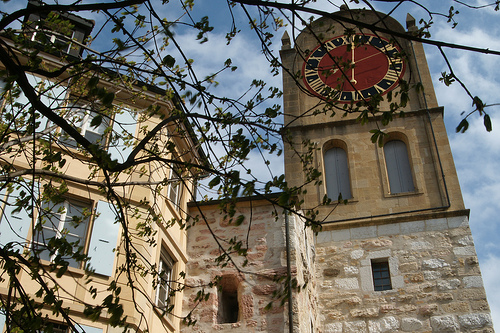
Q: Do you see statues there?
A: No, there are no statues.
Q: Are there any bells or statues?
A: No, there are no statues or bells.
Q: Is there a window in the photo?
A: Yes, there is a window.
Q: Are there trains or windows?
A: Yes, there is a window.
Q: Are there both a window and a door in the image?
A: No, there is a window but no doors.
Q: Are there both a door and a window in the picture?
A: No, there is a window but no doors.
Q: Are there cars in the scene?
A: No, there are no cars.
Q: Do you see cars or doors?
A: No, there are no cars or doors.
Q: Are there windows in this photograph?
A: Yes, there is a window.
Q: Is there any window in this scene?
A: Yes, there is a window.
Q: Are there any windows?
A: Yes, there is a window.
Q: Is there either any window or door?
A: Yes, there is a window.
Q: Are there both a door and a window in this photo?
A: No, there is a window but no doors.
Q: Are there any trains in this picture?
A: No, there are no trains.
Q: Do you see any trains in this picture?
A: No, there are no trains.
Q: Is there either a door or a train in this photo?
A: No, there are no trains or doors.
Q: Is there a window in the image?
A: Yes, there is a window.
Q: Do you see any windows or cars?
A: Yes, there is a window.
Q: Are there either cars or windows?
A: Yes, there is a window.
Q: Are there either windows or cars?
A: Yes, there is a window.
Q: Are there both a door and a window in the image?
A: No, there is a window but no doors.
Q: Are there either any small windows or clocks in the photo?
A: Yes, there is a small window.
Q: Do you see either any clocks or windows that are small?
A: Yes, the window is small.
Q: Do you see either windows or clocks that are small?
A: Yes, the window is small.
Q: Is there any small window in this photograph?
A: Yes, there is a small window.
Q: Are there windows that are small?
A: Yes, there is a window that is small.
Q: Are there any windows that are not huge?
A: Yes, there is a small window.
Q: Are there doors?
A: No, there are no doors.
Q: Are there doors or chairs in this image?
A: No, there are no doors or chairs.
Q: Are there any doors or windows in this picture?
A: Yes, there is a window.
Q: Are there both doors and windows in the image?
A: No, there is a window but no doors.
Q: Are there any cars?
A: No, there are no cars.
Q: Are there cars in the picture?
A: No, there are no cars.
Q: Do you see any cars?
A: No, there are no cars.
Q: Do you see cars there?
A: No, there are no cars.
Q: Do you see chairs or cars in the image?
A: No, there are no cars or chairs.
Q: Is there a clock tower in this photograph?
A: Yes, there is a clock tower.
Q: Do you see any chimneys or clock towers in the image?
A: Yes, there is a clock tower.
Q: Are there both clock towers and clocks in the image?
A: Yes, there are both a clock tower and a clock.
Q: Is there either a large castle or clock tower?
A: Yes, there is a large clock tower.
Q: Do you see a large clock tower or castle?
A: Yes, there is a large clock tower.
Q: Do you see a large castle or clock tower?
A: Yes, there is a large clock tower.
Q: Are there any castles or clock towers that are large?
A: Yes, the clock tower is large.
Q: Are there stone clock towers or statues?
A: Yes, there is a stone clock tower.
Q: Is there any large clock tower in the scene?
A: Yes, there is a large clock tower.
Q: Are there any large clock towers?
A: Yes, there is a large clock tower.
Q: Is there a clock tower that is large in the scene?
A: Yes, there is a large clock tower.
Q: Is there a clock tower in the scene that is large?
A: Yes, there is a clock tower that is large.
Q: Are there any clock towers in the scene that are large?
A: Yes, there is a clock tower that is large.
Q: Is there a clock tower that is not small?
A: Yes, there is a large clock tower.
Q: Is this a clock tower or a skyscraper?
A: This is a clock tower.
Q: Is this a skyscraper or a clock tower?
A: This is a clock tower.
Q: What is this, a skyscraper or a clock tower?
A: This is a clock tower.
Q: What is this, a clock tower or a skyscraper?
A: This is a clock tower.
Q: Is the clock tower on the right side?
A: Yes, the clock tower is on the right of the image.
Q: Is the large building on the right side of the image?
A: Yes, the clock tower is on the right of the image.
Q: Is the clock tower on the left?
A: No, the clock tower is on the right of the image.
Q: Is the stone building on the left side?
A: No, the clock tower is on the right of the image.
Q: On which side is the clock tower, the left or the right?
A: The clock tower is on the right of the image.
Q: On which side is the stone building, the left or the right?
A: The clock tower is on the right of the image.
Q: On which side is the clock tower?
A: The clock tower is on the right of the image.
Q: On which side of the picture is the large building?
A: The clock tower is on the right of the image.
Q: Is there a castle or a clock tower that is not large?
A: No, there is a clock tower but it is large.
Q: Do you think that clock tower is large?
A: Yes, the clock tower is large.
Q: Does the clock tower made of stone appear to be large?
A: Yes, the clock tower is large.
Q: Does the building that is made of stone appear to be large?
A: Yes, the clock tower is large.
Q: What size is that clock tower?
A: The clock tower is large.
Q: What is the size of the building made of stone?
A: The clock tower is large.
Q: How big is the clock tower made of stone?
A: The clock tower is large.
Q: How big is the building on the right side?
A: The clock tower is large.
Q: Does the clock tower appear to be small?
A: No, the clock tower is large.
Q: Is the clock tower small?
A: No, the clock tower is large.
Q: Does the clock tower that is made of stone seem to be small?
A: No, the clock tower is large.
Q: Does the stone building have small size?
A: No, the clock tower is large.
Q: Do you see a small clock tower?
A: No, there is a clock tower but it is large.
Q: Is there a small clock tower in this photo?
A: No, there is a clock tower but it is large.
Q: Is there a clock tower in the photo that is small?
A: No, there is a clock tower but it is large.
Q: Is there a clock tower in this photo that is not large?
A: No, there is a clock tower but it is large.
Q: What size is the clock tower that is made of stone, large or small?
A: The clock tower is large.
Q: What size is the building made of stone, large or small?
A: The clock tower is large.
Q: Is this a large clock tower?
A: Yes, this is a large clock tower.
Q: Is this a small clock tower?
A: No, this is a large clock tower.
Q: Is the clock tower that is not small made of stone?
A: Yes, the clock tower is made of stone.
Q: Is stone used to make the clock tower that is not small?
A: Yes, the clock tower is made of stone.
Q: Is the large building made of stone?
A: Yes, the clock tower is made of stone.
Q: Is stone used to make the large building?
A: Yes, the clock tower is made of stone.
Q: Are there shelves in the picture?
A: No, there are no shelves.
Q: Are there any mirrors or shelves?
A: No, there are no shelves or mirrors.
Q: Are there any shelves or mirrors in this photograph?
A: No, there are no shelves or mirrors.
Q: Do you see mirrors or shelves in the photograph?
A: No, there are no shelves or mirrors.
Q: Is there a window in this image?
A: Yes, there is a window.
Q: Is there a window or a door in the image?
A: Yes, there is a window.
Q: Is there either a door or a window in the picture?
A: Yes, there is a window.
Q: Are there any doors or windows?
A: Yes, there is a window.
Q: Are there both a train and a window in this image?
A: No, there is a window but no trains.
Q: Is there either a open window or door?
A: Yes, there is an open window.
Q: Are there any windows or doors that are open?
A: Yes, the window is open.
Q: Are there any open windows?
A: Yes, there is an open window.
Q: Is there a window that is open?
A: Yes, there is a window that is open.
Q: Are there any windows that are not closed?
A: Yes, there is a open window.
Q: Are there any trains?
A: No, there are no trains.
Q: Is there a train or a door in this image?
A: No, there are no trains or doors.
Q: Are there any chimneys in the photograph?
A: No, there are no chimneys.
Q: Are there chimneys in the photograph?
A: No, there are no chimneys.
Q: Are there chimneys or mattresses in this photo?
A: No, there are no chimneys or mattresses.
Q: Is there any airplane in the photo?
A: No, there are no airplanes.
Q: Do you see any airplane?
A: No, there are no airplanes.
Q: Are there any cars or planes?
A: No, there are no planes or cars.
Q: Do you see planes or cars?
A: No, there are no planes or cars.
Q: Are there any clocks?
A: Yes, there is a clock.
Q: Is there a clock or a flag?
A: Yes, there is a clock.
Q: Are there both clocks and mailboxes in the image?
A: No, there is a clock but no mailboxes.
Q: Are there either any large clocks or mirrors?
A: Yes, there is a large clock.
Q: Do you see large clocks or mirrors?
A: Yes, there is a large clock.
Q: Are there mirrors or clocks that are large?
A: Yes, the clock is large.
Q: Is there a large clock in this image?
A: Yes, there is a large clock.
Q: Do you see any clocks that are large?
A: Yes, there is a large clock.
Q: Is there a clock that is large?
A: Yes, there is a clock that is large.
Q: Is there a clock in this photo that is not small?
A: Yes, there is a large clock.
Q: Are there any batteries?
A: No, there are no batteries.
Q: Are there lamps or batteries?
A: No, there are no batteries or lamps.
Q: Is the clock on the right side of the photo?
A: Yes, the clock is on the right of the image.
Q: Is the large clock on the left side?
A: No, the clock is on the right of the image.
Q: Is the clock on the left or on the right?
A: The clock is on the right of the image.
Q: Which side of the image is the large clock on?
A: The clock is on the right of the image.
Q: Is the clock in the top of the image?
A: Yes, the clock is in the top of the image.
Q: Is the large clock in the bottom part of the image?
A: No, the clock is in the top of the image.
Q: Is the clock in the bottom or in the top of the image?
A: The clock is in the top of the image.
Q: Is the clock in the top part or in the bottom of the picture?
A: The clock is in the top of the image.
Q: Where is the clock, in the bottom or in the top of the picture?
A: The clock is in the top of the image.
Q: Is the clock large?
A: Yes, the clock is large.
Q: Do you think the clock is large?
A: Yes, the clock is large.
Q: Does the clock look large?
A: Yes, the clock is large.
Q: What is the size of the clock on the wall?
A: The clock is large.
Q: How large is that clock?
A: The clock is large.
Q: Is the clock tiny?
A: No, the clock is large.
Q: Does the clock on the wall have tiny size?
A: No, the clock is large.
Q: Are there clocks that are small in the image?
A: No, there is a clock but it is large.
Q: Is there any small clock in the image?
A: No, there is a clock but it is large.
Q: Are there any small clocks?
A: No, there is a clock but it is large.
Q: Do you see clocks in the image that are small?
A: No, there is a clock but it is large.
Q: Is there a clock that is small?
A: No, there is a clock but it is large.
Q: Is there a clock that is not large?
A: No, there is a clock but it is large.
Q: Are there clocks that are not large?
A: No, there is a clock but it is large.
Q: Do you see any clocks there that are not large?
A: No, there is a clock but it is large.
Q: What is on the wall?
A: The clock is on the wall.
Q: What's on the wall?
A: The clock is on the wall.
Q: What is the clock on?
A: The clock is on the wall.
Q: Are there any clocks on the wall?
A: Yes, there is a clock on the wall.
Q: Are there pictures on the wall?
A: No, there is a clock on the wall.